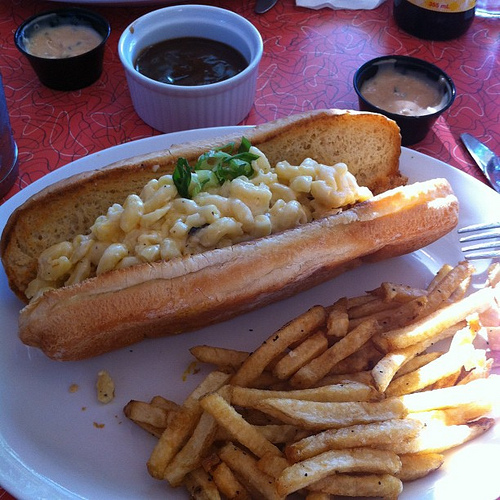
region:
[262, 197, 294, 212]
macaroni and cheese in bread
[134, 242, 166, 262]
macaroni and cheese in bread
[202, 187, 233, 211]
macaroni and cheese in bread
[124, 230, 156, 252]
macaroni and cheese in bread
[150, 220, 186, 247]
macaroni and cheese in bread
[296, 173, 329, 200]
macaroni and cheese in bread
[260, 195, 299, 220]
macaroni and cheese in bread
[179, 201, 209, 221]
macaroni and cheese in bread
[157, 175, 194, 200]
macaroni and cheese in bread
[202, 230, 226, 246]
macaroni and cheese in bread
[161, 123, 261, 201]
Parsley flakes on the macaroni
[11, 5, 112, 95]
A black small cup of dipping sauce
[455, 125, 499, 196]
A knife laying on the table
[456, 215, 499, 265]
Four prongs of a fork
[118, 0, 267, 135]
A white container full of dipping sauce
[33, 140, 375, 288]
Macaroni with parsley flakes in it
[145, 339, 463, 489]
A batch of french fries on a plate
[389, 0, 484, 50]
A bottle of sauce sitting on the table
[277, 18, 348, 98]
A red table with scribble designs on it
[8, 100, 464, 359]
Hot dog bun with macaroni in it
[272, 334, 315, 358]
the fries are golden brown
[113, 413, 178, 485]
the fries are on the plate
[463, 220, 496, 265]
the fork is silver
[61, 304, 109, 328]
the bun is light brown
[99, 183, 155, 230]
the macarooni is in the bun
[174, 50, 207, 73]
the sauce is brown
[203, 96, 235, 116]
the container is white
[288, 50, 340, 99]
the table has squiggly lines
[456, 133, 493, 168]
the knife is on the table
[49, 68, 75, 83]
the bowl is black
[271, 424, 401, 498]
crispy french fry on plate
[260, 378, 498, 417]
crispy french fry on plate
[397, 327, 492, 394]
crispy french fry on plate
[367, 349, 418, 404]
crispy french fry on plate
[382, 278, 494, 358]
crispy french fry on plate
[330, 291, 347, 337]
crispy french fry on plate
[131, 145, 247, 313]
white macaroni on bun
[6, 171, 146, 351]
white macaroni on bun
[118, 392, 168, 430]
crispy french fry on plate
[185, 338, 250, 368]
crispy french fry on plate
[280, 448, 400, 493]
golden cooked french fry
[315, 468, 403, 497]
golden cooked french fry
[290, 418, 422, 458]
golden cooked french fry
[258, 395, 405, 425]
golden cooked french fry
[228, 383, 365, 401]
golden cooked french fry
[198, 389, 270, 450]
golden cooked french fry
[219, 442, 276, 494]
golden cooked french fry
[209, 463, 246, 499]
golden cooked french fry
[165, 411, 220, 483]
golden cooked french fry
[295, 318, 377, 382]
golden cooked french fry